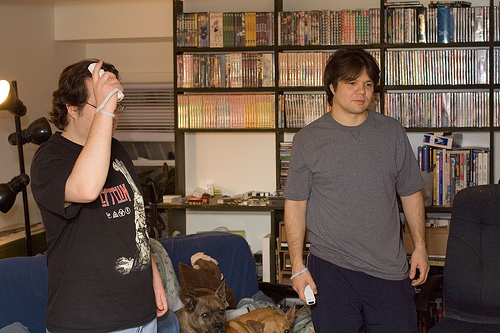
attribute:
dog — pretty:
[179, 276, 229, 332]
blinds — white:
[107, 79, 175, 145]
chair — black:
[429, 185, 499, 330]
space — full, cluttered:
[172, 0, 499, 291]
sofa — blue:
[0, 232, 305, 331]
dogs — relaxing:
[177, 282, 302, 332]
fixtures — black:
[0, 76, 54, 260]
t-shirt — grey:
[285, 110, 427, 280]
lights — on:
[0, 77, 27, 117]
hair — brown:
[47, 56, 122, 132]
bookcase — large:
[173, 2, 497, 286]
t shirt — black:
[30, 130, 157, 332]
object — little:
[181, 13, 184, 45]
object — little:
[206, 182, 213, 196]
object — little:
[422, 133, 452, 149]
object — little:
[416, 8, 425, 43]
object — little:
[326, 11, 330, 45]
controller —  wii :
[86, 60, 124, 117]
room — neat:
[5, 3, 499, 326]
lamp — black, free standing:
[3, 85, 46, 247]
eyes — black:
[201, 298, 226, 322]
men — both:
[278, 45, 438, 328]